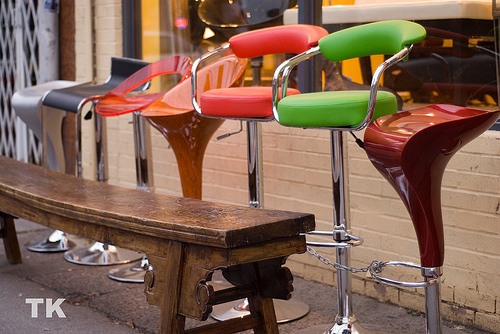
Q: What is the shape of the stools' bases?
A: Round.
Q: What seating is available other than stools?
A: Bench.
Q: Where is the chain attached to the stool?
A: Foot rail.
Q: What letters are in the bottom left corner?
A: TK.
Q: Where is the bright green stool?
A: Second from right.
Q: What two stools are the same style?
A: The orange and green ones.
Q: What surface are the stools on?
A: Concrete.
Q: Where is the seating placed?
A: Sidewalk.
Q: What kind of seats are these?
A: Barstools.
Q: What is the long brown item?
A: Bench.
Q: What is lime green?
A: Seat cushion.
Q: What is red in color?
A: Bar stool.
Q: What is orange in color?
A: Bar stool.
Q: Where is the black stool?
A: Second to last.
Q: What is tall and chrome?
A: Stools.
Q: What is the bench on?
A: Sidewalk.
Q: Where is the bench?
A: Outside on the sidewalk.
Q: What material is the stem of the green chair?
A: Chrome.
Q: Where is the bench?
A: The bench is in front of the stools.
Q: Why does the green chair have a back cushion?
A: For comfort.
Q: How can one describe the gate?
A: The gate is painted white.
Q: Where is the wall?
A: Behind the chairs.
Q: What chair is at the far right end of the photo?
A: A red chrome stool.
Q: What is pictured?
A: Seats.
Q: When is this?
A: Daytime.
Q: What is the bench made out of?
A: Wood.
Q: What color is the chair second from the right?
A: Green.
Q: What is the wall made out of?
A: Brick.